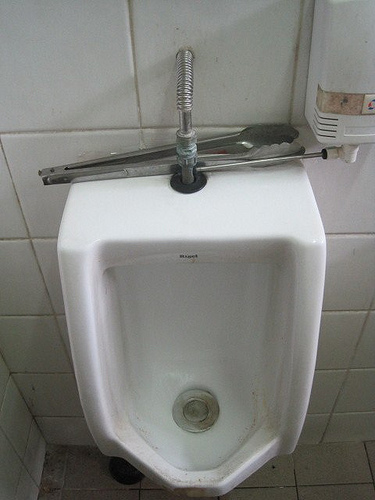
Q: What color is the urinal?
A: White.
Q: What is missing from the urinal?
A: Parts.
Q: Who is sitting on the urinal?
A: No one.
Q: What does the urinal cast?
A: Shadow.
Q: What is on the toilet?
A: Tongs.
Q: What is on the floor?
A: Tile.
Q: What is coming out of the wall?
A: Water line.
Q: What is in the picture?
A: Urinal.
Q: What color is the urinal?
A: White.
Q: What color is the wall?
A: White.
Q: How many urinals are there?
A: 1.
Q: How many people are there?
A: None.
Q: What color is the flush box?
A: White.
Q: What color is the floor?
A: Beige.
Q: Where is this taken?
A: A bathroom.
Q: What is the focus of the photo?
A: A urinal.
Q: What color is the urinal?
A: White.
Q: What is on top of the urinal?
A: Tongs.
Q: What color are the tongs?
A: Silver.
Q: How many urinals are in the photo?
A: One.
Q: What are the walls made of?
A: Tile.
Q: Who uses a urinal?
A: Men.